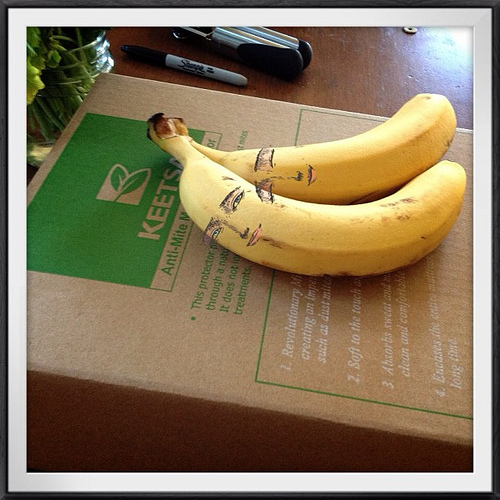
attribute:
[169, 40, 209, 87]
sharpie — black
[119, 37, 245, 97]
marker — black, grey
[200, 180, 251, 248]
eyes — open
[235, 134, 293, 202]
eyes — closed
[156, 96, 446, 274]
two — yellow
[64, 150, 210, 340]
box — brown, cardboard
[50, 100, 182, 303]
logo — green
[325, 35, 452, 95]
table — brown, wooden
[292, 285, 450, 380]
writing — white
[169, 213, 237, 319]
writing — blue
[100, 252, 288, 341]
print — green